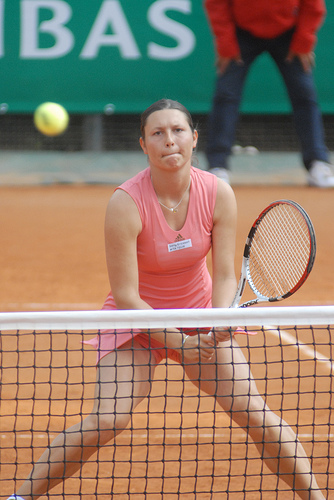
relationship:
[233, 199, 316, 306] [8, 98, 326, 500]
racket of player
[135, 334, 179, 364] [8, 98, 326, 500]
bloomers of player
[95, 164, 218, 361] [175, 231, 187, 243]
clothing by adidas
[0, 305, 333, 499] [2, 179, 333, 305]
net of court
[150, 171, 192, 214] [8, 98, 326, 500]
necklace of player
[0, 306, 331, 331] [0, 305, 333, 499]
top of net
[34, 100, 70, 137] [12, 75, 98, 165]
ball in air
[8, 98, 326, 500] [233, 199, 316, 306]
player holding racket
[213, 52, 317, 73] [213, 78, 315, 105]
hands on knees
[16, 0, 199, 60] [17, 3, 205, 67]
letters say bas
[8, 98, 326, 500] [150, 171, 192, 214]
player wearing necklace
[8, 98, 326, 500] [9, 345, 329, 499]
player has legs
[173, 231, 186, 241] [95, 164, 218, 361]
symbol on clothing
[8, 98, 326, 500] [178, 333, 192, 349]
player wearing bracelet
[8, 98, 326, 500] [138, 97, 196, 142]
player has hair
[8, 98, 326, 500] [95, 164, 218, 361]
player wearing pink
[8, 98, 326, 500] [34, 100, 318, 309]
player playing tennis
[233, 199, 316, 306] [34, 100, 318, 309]
racket for tennis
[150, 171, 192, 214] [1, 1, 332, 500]
necklace in picture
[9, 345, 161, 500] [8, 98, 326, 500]
legs of player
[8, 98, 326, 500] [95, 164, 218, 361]
player wears clothing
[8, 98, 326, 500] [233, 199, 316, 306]
player grips racket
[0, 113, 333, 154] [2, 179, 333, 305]
fence behind court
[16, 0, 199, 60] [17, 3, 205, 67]
letters saying bas